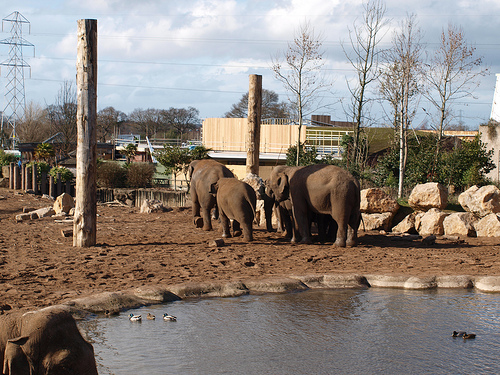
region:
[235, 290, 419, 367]
this is a pool of water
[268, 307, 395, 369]
there are ripples of water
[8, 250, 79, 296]
the ground is sandy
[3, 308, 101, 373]
the elephant is drinking water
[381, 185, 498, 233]
these are some rocks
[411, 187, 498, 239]
the rocks are big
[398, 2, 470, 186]
these are two trees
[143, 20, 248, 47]
this is the sky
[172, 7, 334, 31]
the sky has clouds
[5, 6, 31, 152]
this is an electricity post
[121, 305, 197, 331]
Three ducks in water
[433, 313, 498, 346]
Two ducks in water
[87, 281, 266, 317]
Gray stones around water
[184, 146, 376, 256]
Three elephants standing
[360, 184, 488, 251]
Brown and gray rocks by elephants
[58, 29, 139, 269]
Brown stump rising out of dirt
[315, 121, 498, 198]
Green bushes next to elephants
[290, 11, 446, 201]
Brown dead trees by elephants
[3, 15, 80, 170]
Power pole in the sky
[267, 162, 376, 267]
Gray and brown elephant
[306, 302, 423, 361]
part of a water pond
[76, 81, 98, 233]
part of a wooden pole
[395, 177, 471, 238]
part of a some rocks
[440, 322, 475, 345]
two ducks in the water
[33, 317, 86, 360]
head of an elephant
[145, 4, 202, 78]
part of the cloudy sky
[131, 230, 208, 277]
part of a brown ground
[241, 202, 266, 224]
tail of an elephant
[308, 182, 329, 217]
stomach of an elephant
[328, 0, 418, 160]
part of a some dry trees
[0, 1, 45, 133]
Group of elephants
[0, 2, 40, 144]
Power transmission tower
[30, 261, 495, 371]
A pond surround by stones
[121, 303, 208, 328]
Ducks swimming on the water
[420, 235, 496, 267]
A patch of brown dirt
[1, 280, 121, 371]
Elephant drinking from pond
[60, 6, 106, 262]
pole made from wood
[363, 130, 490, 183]
green bushes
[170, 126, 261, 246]
An elephant walking behind a larger elephant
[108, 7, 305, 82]
Patch of partly cloudy sky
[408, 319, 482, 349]
Two ducks swimming in the water.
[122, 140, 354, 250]
Three elephants walking on sand.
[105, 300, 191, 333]
Three ducks swimming in the water.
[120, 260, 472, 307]
Rock barrier surrounding water.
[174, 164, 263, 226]
Small elephant following bigger elephant.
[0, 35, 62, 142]
Tall silver electric tower.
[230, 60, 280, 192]
Tall wooden post .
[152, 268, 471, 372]
Pond of water with swimming ducks in it.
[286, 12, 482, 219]
Four trees beside the elephants.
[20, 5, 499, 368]
Elephants and ducks in an enclosed area.